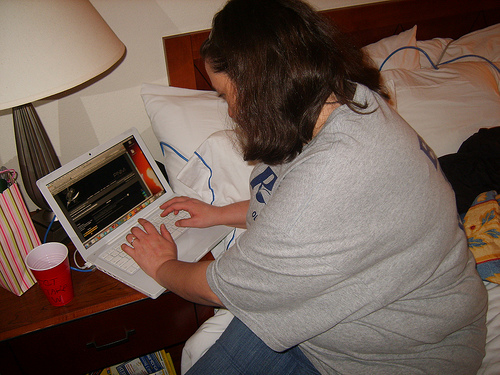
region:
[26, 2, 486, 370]
A person is in their bedroom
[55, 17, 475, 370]
A person is using their computer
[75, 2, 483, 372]
A person is sitting on a bed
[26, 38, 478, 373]
A person is typing on a laptop computer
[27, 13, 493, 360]
A person is watching the computer screen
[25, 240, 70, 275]
A cup in somebody's bedroom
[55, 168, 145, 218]
The screen on somebody's computer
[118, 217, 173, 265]
Somebody's hand is typing something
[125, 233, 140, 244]
A ring on somebody's finger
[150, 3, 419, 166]
Somebody has brown colored hair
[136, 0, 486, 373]
Brown haired woman sitting on bed.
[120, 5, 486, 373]
Woman wearing grey shirt and jeans.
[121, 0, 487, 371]
Brown haired woman typing.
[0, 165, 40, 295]
Bag with pink, brown and yellow stripes.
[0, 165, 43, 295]
Colorful gift bag on nightstand.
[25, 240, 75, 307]
Plastic cup that has been written on.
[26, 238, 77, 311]
Red plastic cup on nightstand.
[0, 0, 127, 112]
Large white lamp shade.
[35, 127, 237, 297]
Grey laptop on nightstand.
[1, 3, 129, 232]
Large lamp with white shade.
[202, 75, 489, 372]
Woman is wearing a gray shirt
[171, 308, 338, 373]
Woman is wearing jeans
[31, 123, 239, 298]
Woman is typing on a laptop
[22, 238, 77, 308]
Red cup on nightstand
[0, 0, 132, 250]
Lamp is on nightstand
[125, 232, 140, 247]
Woman wearing a wedding ring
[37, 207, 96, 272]
Cords are behind the laptop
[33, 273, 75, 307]
Words written on cup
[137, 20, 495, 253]
White pillows are on the bed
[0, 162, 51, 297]
Bag on the nightstand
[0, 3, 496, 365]
woman is on a laptop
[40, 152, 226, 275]
the laptop is white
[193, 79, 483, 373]
woman's shirt is gray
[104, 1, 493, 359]
woman sitting on a bed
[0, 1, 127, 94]
lamp shade is white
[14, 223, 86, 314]
red cup on table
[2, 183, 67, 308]
striped bag behind cup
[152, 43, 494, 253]
blue cord on pillow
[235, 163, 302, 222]
blue letters on shirt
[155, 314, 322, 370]
woman is wearing blue jeans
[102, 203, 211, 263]
left hand of woman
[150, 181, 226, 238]
right hand of woman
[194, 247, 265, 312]
left elbow of woman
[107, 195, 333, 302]
left arm of woman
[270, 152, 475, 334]
gray shirt of woman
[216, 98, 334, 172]
brunette hair of woman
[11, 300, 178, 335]
brown table under computer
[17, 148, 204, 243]
screen of the laptop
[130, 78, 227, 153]
white pillow in back